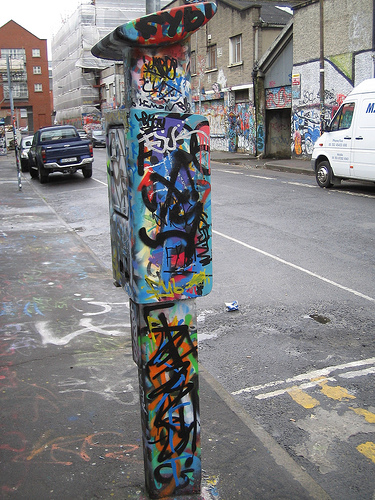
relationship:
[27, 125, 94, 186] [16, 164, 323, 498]
truck on curb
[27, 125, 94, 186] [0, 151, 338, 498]
truck parked near curb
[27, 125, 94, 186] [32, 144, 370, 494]
truck parked in street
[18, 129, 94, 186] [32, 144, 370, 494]
truck parked in street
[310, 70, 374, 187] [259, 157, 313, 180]
van on curb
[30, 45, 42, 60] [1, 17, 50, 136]
window attached to building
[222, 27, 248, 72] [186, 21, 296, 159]
window attached to building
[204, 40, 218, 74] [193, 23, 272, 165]
window attached to building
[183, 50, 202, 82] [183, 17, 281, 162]
window attached to building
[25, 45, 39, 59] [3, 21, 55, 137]
window attached to building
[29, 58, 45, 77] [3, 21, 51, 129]
window attached to building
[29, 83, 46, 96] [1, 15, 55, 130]
window attached to building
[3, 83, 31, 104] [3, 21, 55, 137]
window attached to building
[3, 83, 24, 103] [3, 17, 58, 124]
window attached to building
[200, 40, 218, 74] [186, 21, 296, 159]
window attached to building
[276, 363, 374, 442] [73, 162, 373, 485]
paint painted on street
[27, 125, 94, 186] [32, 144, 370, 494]
truck on top of street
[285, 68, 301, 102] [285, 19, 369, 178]
sign attached to wall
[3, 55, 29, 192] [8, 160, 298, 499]
post attached to sidewalk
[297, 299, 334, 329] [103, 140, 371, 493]
spot on top of street